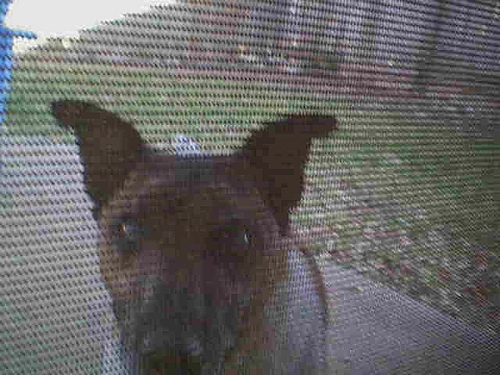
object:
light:
[3, 0, 169, 52]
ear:
[234, 111, 338, 231]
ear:
[50, 99, 147, 220]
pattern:
[0, 1, 500, 374]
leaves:
[429, 131, 441, 139]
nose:
[133, 327, 199, 370]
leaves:
[373, 154, 386, 163]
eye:
[118, 215, 145, 243]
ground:
[0, 131, 500, 373]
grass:
[0, 37, 500, 335]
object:
[0, 0, 40, 119]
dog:
[48, 97, 338, 373]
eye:
[223, 223, 254, 259]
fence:
[0, 0, 500, 374]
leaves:
[464, 187, 477, 196]